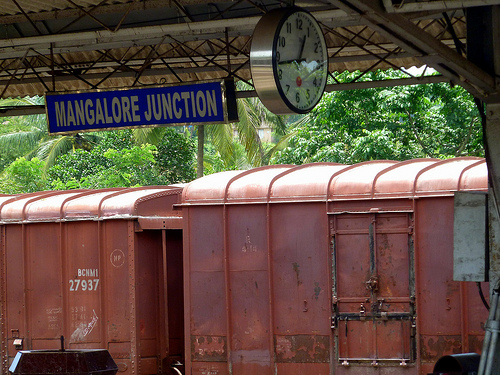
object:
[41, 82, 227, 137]
sign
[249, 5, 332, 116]
clock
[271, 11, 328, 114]
12:43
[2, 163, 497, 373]
train car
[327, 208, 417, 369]
door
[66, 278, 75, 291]
writing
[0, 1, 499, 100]
awning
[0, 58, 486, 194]
greenery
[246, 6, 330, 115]
metal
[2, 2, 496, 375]
train station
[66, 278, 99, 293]
number 27937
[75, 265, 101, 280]
white letters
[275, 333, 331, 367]
paint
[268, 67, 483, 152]
leaves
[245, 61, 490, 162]
tree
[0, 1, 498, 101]
ceiling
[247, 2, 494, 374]
right side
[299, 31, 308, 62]
hand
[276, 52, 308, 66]
hand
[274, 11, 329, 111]
white face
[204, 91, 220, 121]
word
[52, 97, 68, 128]
letter m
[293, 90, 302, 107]
number 6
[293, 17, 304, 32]
number 12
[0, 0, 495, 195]
background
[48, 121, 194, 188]
tree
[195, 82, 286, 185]
tree